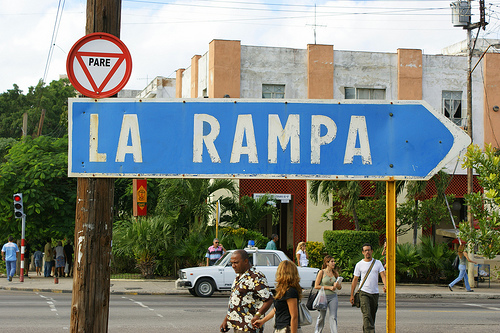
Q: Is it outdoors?
A: Yes, it is outdoors.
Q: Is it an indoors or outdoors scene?
A: It is outdoors.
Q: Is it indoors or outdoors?
A: It is outdoors.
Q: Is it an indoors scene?
A: No, it is outdoors.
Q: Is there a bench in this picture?
A: No, there are no benches.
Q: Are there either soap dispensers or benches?
A: No, there are no benches or soap dispensers.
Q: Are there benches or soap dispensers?
A: No, there are no benches or soap dispensers.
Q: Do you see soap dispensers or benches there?
A: No, there are no benches or soap dispensers.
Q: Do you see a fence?
A: No, there are no fences.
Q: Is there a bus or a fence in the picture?
A: No, there are no fences or buses.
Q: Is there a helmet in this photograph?
A: No, there are no helmets.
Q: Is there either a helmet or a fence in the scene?
A: No, there are no helmets or fences.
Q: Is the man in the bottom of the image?
A: Yes, the man is in the bottom of the image.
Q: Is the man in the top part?
A: No, the man is in the bottom of the image.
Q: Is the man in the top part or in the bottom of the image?
A: The man is in the bottom of the image.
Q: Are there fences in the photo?
A: No, there are no fences.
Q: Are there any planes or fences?
A: No, there are no fences or planes.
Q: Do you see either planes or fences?
A: No, there are no fences or planes.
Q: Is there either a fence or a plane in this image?
A: No, there are no fences or airplanes.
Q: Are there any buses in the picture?
A: No, there are no buses.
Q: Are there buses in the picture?
A: No, there are no buses.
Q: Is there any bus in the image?
A: No, there are no buses.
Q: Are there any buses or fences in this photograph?
A: No, there are no buses or fences.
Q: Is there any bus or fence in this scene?
A: No, there are no buses or fences.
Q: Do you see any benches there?
A: No, there are no benches.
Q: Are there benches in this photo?
A: No, there are no benches.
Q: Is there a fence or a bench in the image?
A: No, there are no benches or fences.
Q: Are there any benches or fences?
A: No, there are no benches or fences.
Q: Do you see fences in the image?
A: No, there are no fences.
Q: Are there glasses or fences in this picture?
A: No, there are no fences or glasses.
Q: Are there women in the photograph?
A: Yes, there is a woman.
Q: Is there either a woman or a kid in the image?
A: Yes, there is a woman.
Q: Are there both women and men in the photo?
A: Yes, there are both a woman and a man.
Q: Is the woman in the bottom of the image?
A: Yes, the woman is in the bottom of the image.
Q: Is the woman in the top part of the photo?
A: No, the woman is in the bottom of the image.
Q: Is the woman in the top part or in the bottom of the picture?
A: The woman is in the bottom of the image.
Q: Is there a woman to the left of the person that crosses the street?
A: Yes, there is a woman to the left of the person.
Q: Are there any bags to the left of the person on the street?
A: No, there is a woman to the left of the person.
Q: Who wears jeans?
A: The woman wears jeans.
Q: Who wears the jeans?
A: The woman wears jeans.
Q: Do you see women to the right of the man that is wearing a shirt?
A: Yes, there is a woman to the right of the man.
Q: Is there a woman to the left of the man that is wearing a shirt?
A: No, the woman is to the right of the man.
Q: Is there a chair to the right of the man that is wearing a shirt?
A: No, there is a woman to the right of the man.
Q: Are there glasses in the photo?
A: No, there are no glasses.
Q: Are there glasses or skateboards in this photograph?
A: No, there are no glasses or skateboards.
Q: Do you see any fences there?
A: No, there are no fences.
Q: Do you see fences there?
A: No, there are no fences.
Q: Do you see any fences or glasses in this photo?
A: No, there are no fences or glasses.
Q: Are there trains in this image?
A: No, there are no trains.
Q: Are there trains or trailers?
A: No, there are no trains or trailers.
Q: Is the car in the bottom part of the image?
A: Yes, the car is in the bottom of the image.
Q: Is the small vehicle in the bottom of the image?
A: Yes, the car is in the bottom of the image.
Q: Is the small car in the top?
A: No, the car is in the bottom of the image.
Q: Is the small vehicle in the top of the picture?
A: No, the car is in the bottom of the image.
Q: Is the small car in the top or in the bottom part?
A: The car is in the bottom of the image.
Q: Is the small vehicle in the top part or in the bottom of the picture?
A: The car is in the bottom of the image.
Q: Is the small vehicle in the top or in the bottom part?
A: The car is in the bottom of the image.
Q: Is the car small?
A: Yes, the car is small.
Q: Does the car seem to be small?
A: Yes, the car is small.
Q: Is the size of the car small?
A: Yes, the car is small.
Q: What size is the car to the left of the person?
A: The car is small.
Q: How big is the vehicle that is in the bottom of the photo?
A: The car is small.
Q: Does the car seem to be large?
A: No, the car is small.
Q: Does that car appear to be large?
A: No, the car is small.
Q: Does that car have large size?
A: No, the car is small.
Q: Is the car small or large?
A: The car is small.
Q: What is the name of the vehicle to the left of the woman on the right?
A: The vehicle is a car.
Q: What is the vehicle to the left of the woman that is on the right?
A: The vehicle is a car.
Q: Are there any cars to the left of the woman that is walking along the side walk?
A: Yes, there is a car to the left of the woman.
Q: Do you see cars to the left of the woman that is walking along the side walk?
A: Yes, there is a car to the left of the woman.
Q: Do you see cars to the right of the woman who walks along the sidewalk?
A: No, the car is to the left of the woman.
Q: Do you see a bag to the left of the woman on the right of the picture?
A: No, there is a car to the left of the woman.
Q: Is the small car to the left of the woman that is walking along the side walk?
A: Yes, the car is to the left of the woman.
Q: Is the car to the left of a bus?
A: No, the car is to the left of the woman.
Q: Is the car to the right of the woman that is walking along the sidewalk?
A: No, the car is to the left of the woman.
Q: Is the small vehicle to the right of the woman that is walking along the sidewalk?
A: No, the car is to the left of the woman.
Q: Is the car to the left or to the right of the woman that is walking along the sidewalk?
A: The car is to the left of the woman.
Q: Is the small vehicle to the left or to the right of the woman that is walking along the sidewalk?
A: The car is to the left of the woman.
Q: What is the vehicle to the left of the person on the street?
A: The vehicle is a car.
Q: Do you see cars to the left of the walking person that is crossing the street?
A: Yes, there is a car to the left of the person.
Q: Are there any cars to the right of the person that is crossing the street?
A: No, the car is to the left of the person.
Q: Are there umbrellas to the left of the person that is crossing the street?
A: No, there is a car to the left of the person.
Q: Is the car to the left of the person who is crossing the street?
A: Yes, the car is to the left of the person.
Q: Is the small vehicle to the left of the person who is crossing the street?
A: Yes, the car is to the left of the person.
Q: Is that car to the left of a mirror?
A: No, the car is to the left of the person.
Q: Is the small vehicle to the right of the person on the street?
A: No, the car is to the left of the person.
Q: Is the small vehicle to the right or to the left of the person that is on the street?
A: The car is to the left of the person.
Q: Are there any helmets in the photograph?
A: No, there are no helmets.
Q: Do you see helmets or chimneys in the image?
A: No, there are no helmets or chimneys.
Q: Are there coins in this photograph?
A: No, there are no coins.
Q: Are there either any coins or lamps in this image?
A: No, there are no coins or lamps.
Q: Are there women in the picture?
A: Yes, there is a woman.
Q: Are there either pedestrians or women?
A: Yes, there is a woman.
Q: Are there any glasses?
A: No, there are no glasses.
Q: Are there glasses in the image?
A: No, there are no glasses.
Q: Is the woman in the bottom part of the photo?
A: Yes, the woman is in the bottom of the image.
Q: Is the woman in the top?
A: No, the woman is in the bottom of the image.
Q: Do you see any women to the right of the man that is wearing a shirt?
A: Yes, there is a woman to the right of the man.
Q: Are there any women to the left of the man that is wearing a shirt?
A: No, the woman is to the right of the man.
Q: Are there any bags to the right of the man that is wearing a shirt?
A: No, there is a woman to the right of the man.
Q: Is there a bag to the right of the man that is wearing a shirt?
A: No, there is a woman to the right of the man.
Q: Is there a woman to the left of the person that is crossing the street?
A: Yes, there is a woman to the left of the person.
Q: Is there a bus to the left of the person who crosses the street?
A: No, there is a woman to the left of the person.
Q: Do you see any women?
A: Yes, there is a woman.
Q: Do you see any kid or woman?
A: Yes, there is a woman.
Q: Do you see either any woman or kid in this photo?
A: Yes, there is a woman.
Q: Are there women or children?
A: Yes, there is a woman.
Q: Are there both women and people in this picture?
A: Yes, there are both a woman and a person.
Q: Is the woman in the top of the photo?
A: No, the woman is in the bottom of the image.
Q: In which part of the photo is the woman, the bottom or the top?
A: The woman is in the bottom of the image.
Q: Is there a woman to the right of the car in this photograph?
A: Yes, there is a woman to the right of the car.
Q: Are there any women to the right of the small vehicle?
A: Yes, there is a woman to the right of the car.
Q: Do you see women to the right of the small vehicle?
A: Yes, there is a woman to the right of the car.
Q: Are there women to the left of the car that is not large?
A: No, the woman is to the right of the car.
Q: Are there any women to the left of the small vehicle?
A: No, the woman is to the right of the car.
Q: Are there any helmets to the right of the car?
A: No, there is a woman to the right of the car.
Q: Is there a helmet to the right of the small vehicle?
A: No, there is a woman to the right of the car.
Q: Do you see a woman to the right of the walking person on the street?
A: Yes, there is a woman to the right of the person.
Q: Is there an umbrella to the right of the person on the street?
A: No, there is a woman to the right of the person.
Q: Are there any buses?
A: No, there are no buses.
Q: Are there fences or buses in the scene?
A: No, there are no buses or fences.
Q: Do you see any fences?
A: No, there are no fences.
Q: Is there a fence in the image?
A: No, there are no fences.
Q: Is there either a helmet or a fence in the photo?
A: No, there are no fences or helmets.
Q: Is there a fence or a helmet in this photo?
A: No, there are no fences or helmets.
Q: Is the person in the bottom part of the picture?
A: Yes, the person is in the bottom of the image.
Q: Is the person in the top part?
A: No, the person is in the bottom of the image.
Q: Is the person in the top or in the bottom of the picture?
A: The person is in the bottom of the image.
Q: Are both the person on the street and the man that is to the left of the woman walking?
A: Yes, both the person and the man are walking.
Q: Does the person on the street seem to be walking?
A: Yes, the person is walking.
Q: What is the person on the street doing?
A: The person is walking.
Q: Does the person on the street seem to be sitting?
A: No, the person is walking.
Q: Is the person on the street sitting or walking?
A: The person is walking.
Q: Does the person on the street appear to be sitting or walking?
A: The person is walking.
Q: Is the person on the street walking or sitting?
A: The person is walking.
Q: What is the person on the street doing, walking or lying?
A: The person is walking.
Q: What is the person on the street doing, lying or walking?
A: The person is walking.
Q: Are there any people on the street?
A: Yes, there is a person on the street.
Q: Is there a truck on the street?
A: No, there is a person on the street.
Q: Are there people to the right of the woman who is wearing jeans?
A: Yes, there is a person to the right of the woman.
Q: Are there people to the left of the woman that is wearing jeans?
A: No, the person is to the right of the woman.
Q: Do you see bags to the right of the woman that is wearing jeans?
A: No, there is a person to the right of the woman.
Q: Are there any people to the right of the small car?
A: Yes, there is a person to the right of the car.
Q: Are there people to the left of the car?
A: No, the person is to the right of the car.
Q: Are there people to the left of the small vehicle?
A: No, the person is to the right of the car.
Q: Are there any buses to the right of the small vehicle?
A: No, there is a person to the right of the car.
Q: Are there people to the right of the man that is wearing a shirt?
A: Yes, there is a person to the right of the man.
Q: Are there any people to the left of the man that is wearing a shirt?
A: No, the person is to the right of the man.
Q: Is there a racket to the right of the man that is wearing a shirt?
A: No, there is a person to the right of the man.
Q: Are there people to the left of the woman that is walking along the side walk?
A: Yes, there is a person to the left of the woman.